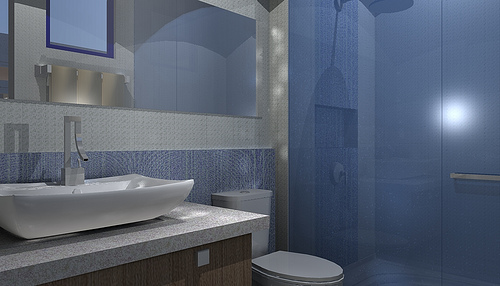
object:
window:
[46, 0, 114, 57]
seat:
[250, 250, 345, 286]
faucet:
[60, 114, 90, 187]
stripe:
[0, 98, 274, 154]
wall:
[0, 0, 280, 258]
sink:
[0, 172, 195, 242]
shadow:
[3, 122, 53, 183]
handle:
[328, 162, 348, 187]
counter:
[0, 200, 273, 286]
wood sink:
[35, 232, 255, 286]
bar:
[445, 170, 497, 184]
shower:
[286, 0, 500, 286]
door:
[270, 0, 500, 286]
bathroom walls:
[372, 0, 500, 286]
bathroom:
[0, 0, 500, 286]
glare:
[432, 94, 479, 136]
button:
[239, 190, 252, 194]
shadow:
[15, 0, 257, 60]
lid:
[251, 250, 345, 284]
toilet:
[210, 186, 345, 286]